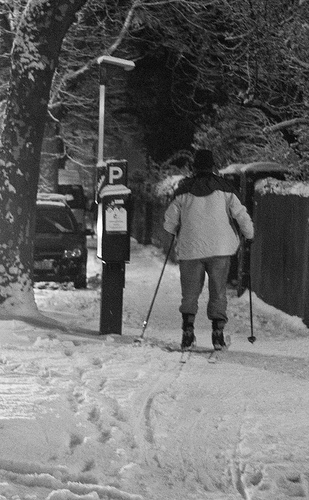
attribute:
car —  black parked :
[30, 199, 95, 288]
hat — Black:
[193, 151, 211, 166]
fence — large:
[129, 182, 308, 332]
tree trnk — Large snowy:
[0, 0, 106, 322]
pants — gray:
[176, 253, 232, 323]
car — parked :
[24, 176, 107, 307]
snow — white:
[146, 384, 190, 417]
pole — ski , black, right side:
[250, 238, 253, 344]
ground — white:
[1, 234, 307, 497]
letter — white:
[108, 165, 122, 184]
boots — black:
[171, 304, 232, 351]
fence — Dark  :
[212, 147, 299, 260]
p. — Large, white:
[108, 164, 126, 182]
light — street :
[92, 54, 139, 100]